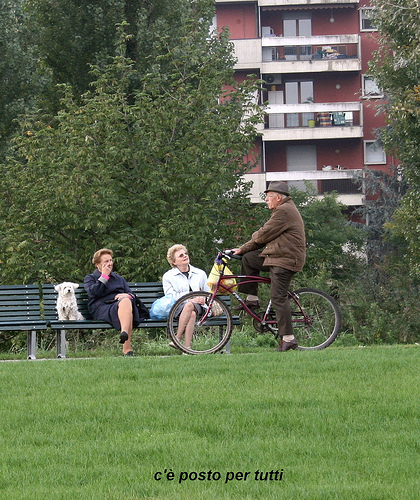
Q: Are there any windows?
A: Yes, there is a window.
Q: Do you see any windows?
A: Yes, there is a window.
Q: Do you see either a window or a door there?
A: Yes, there is a window.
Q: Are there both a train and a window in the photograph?
A: No, there is a window but no trains.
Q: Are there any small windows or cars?
A: Yes, there is a small window.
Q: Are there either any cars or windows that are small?
A: Yes, the window is small.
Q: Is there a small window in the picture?
A: Yes, there is a small window.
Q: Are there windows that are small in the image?
A: Yes, there is a small window.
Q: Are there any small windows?
A: Yes, there is a small window.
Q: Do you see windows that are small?
A: Yes, there is a small window.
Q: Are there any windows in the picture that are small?
A: Yes, there is a window that is small.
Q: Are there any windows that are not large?
A: Yes, there is a small window.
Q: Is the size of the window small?
A: Yes, the window is small.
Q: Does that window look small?
A: Yes, the window is small.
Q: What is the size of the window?
A: The window is small.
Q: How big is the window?
A: The window is small.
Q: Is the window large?
A: No, the window is small.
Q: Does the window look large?
A: No, the window is small.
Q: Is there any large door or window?
A: No, there is a window but it is small.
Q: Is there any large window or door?
A: No, there is a window but it is small.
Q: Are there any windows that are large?
A: No, there is a window but it is small.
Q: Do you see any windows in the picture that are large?
A: No, there is a window but it is small.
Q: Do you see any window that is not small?
A: No, there is a window but it is small.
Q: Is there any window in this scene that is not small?
A: No, there is a window but it is small.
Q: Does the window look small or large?
A: The window is small.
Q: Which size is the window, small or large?
A: The window is small.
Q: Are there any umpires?
A: No, there are no umpires.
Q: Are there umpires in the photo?
A: No, there are no umpires.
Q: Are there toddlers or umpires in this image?
A: No, there are no umpires or toddlers.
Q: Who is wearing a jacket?
A: The man is wearing a jacket.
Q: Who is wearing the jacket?
A: The man is wearing a jacket.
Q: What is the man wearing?
A: The man is wearing a jacket.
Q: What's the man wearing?
A: The man is wearing a jacket.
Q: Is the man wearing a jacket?
A: Yes, the man is wearing a jacket.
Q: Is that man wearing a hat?
A: No, the man is wearing a jacket.